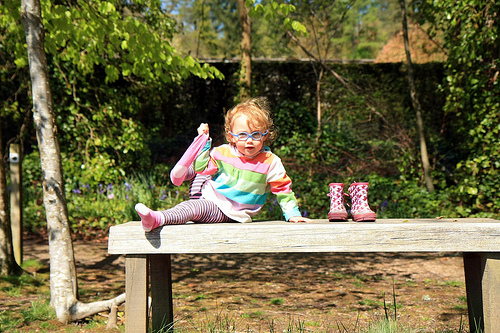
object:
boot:
[328, 183, 348, 222]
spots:
[337, 188, 341, 193]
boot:
[348, 181, 376, 222]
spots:
[363, 196, 367, 202]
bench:
[106, 217, 499, 332]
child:
[134, 97, 316, 232]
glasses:
[229, 130, 269, 141]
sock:
[170, 129, 210, 186]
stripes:
[160, 161, 241, 225]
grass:
[149, 284, 483, 333]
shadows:
[32, 251, 459, 316]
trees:
[236, 1, 497, 217]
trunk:
[18, 0, 123, 329]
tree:
[4, 4, 219, 322]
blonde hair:
[224, 100, 279, 147]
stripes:
[192, 137, 302, 224]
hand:
[288, 216, 315, 223]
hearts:
[361, 185, 366, 189]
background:
[0, 0, 498, 242]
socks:
[134, 202, 165, 231]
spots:
[356, 205, 361, 210]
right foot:
[170, 160, 191, 186]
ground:
[3, 228, 496, 332]